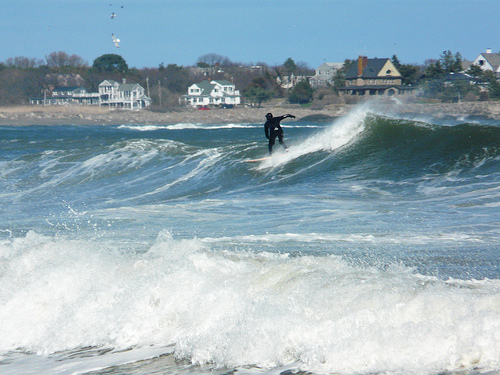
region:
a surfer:
[253, 101, 302, 167]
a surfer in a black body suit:
[253, 106, 315, 185]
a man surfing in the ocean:
[229, 100, 332, 196]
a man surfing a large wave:
[236, 85, 473, 195]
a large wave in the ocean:
[8, 206, 496, 362]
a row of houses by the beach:
[15, 59, 483, 139]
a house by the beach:
[322, 39, 414, 111]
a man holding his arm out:
[250, 103, 320, 177]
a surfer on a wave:
[69, 90, 466, 192]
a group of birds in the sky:
[86, 0, 143, 61]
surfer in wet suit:
[244, 98, 285, 170]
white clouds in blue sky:
[18, 19, 56, 46]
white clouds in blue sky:
[284, 8, 336, 55]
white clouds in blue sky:
[397, 38, 414, 49]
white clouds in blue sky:
[437, 3, 467, 28]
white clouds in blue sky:
[344, 3, 414, 45]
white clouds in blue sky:
[217, 12, 264, 54]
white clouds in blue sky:
[297, 22, 332, 43]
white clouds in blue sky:
[252, 31, 323, 66]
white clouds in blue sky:
[187, 9, 238, 33]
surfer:
[234, 93, 299, 151]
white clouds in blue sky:
[430, 3, 494, 60]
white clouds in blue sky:
[395, 13, 457, 40]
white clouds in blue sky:
[332, 12, 387, 32]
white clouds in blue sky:
[324, 8, 376, 45]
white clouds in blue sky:
[268, 31, 316, 52]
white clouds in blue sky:
[207, 19, 282, 46]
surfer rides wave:
[259, 111, 294, 161]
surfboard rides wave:
[244, 149, 292, 163]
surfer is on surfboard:
[260, 111, 297, 149]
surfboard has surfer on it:
[238, 153, 280, 164]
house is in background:
[94, 77, 151, 112]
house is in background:
[174, 76, 241, 110]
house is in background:
[337, 55, 402, 98]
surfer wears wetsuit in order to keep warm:
[237, 107, 292, 162]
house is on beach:
[87, 76, 152, 111]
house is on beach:
[176, 75, 240, 107]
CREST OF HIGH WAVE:
[322, 108, 413, 154]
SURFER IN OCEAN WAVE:
[258, 108, 297, 157]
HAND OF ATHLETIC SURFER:
[283, 111, 295, 121]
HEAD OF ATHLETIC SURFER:
[261, 111, 273, 118]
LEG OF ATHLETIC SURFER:
[266, 134, 274, 151]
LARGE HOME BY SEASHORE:
[184, 76, 244, 113]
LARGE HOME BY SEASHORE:
[93, 74, 153, 114]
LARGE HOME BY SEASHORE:
[334, 51, 415, 102]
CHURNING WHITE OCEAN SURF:
[190, 258, 260, 315]